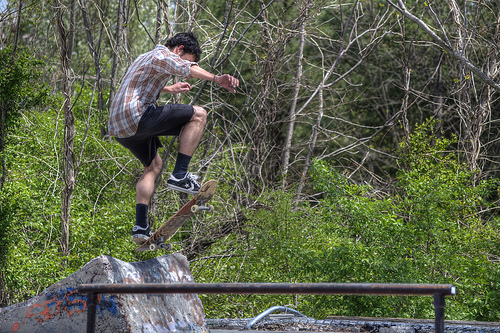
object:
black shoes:
[167, 175, 209, 191]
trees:
[0, 4, 498, 267]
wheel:
[149, 243, 158, 252]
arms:
[157, 55, 216, 81]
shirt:
[108, 44, 195, 139]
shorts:
[112, 103, 196, 167]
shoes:
[132, 225, 153, 241]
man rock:
[1, 254, 202, 333]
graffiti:
[2, 292, 126, 333]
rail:
[72, 282, 454, 331]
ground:
[333, 126, 455, 261]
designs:
[165, 221, 179, 233]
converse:
[157, 163, 216, 197]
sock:
[172, 151, 193, 179]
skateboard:
[134, 179, 219, 254]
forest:
[1, 1, 498, 318]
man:
[108, 31, 239, 243]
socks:
[132, 202, 149, 231]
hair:
[164, 31, 203, 63]